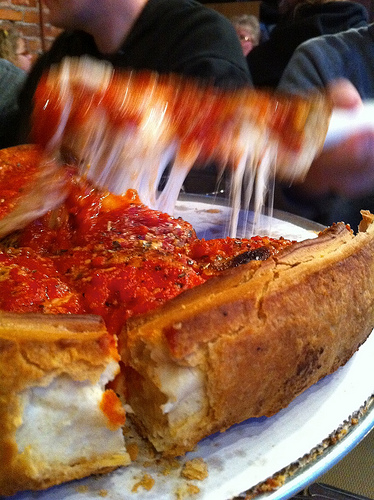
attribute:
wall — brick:
[0, 0, 82, 87]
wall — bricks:
[2, 11, 78, 80]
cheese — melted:
[52, 57, 274, 234]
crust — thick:
[1, 309, 132, 495]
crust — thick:
[106, 208, 372, 453]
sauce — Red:
[98, 224, 153, 307]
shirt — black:
[14, 2, 254, 207]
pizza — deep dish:
[4, 141, 373, 498]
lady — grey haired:
[234, 12, 261, 44]